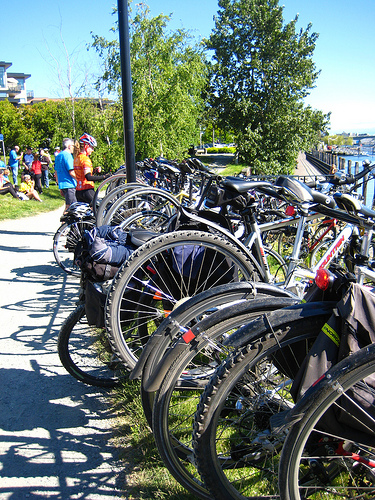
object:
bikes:
[269, 334, 375, 499]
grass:
[96, 222, 375, 500]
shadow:
[0, 225, 194, 500]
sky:
[0, 0, 375, 137]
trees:
[84, 0, 208, 171]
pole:
[114, 0, 138, 208]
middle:
[93, 0, 238, 170]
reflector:
[180, 326, 198, 346]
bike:
[129, 158, 375, 463]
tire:
[141, 294, 361, 500]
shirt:
[73, 152, 95, 192]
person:
[71, 130, 114, 206]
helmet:
[79, 131, 98, 149]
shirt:
[54, 149, 77, 190]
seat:
[224, 179, 273, 195]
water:
[331, 153, 375, 214]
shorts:
[60, 188, 78, 207]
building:
[0, 59, 34, 106]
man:
[53, 137, 79, 218]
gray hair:
[62, 136, 74, 149]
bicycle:
[103, 162, 375, 384]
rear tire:
[102, 225, 268, 391]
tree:
[196, 0, 334, 185]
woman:
[18, 172, 43, 203]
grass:
[0, 178, 64, 219]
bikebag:
[288, 277, 373, 447]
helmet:
[59, 200, 95, 225]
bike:
[102, 154, 374, 258]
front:
[277, 148, 375, 293]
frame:
[238, 198, 360, 286]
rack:
[223, 161, 375, 250]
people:
[7, 143, 23, 189]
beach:
[293, 130, 374, 222]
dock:
[304, 139, 348, 156]